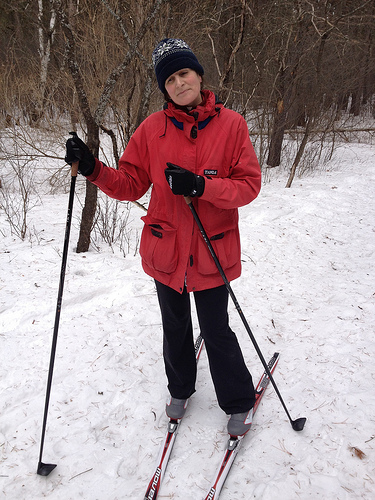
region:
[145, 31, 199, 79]
blue and white knit hat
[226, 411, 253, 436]
a gray ski boot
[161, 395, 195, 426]
a gray ski boot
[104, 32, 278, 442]
a woman wearing a red jacket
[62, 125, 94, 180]
a gloved hand holding a ski pole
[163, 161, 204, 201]
a gloved hand holding a ski pole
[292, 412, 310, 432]
black disc support on pole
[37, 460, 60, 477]
black disc support on ski pole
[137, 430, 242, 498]
red and white skis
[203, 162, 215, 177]
a black patch on a red jacket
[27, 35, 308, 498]
female skiier posing for a picture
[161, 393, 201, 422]
gray, red and white ski boot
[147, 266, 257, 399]
warm, black, womens ski pants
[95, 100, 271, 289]
well insulated, thick, red women's ski coat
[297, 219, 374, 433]
a thin covering of snow with grass poking through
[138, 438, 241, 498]
red, black and white cross country skis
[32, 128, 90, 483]
tall black ski pole with brown handle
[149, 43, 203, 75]
warm ski hat with a snowflake design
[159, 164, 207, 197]
warm, black womens gloves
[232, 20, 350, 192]
an assortment of trees without leaves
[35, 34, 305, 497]
a woman cross country skiing in the woods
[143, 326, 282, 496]
white red and black skis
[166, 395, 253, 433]
gray and white boots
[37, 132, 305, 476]
a woman holding two black ski poles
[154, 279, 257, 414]
woman wearing black ski pants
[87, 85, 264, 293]
woman wearing a red ski coat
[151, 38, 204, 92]
a white and blue wool hat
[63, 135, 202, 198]
woman wearing black gloves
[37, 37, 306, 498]
a woman standing in the snow on skis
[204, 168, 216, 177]
a black and white logo on a red coat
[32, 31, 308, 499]
Person skiing standing next to trees.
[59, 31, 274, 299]
Red coat on woman skiing.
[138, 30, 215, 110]
Woman wearing a black stocking cap.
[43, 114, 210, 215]
Woman wearing black gloves.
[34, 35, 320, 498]
Woman resting on ski poles.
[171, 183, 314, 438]
Ski pole with resting skier.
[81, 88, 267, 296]
Velcro pockets on the red coat.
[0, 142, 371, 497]
Skier on forest path.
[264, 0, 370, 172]
Trees in among the snow fall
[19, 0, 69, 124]
Birch tree in the winter forest.